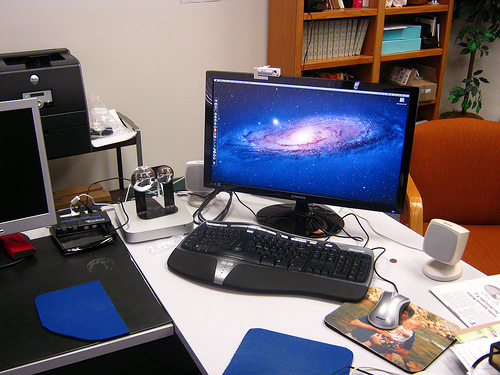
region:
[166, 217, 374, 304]
a black computer keyboard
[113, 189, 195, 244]
an Apple Mac Mini computer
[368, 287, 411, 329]
a silver corded computer mouse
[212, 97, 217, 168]
Apple Mac OS X dock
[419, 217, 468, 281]
a small computer speaker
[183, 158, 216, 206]
a small computer speaker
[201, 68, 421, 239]
a black computer monitor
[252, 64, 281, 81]
a clip on web cam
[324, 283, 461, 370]
a computer mouse pad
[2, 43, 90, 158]
a black laser printer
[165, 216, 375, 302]
Black keyboard for computer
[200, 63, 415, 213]
Black framed computer monitor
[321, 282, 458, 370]
Mouse pad with family photo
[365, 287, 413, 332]
Silver computer mouse on pad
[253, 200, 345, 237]
Black base of computer monitor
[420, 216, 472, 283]
Small white, exterior computer speaker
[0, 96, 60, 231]
Part of silver framed computer monitor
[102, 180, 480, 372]
White tabletop under computer equipment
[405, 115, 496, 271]
Rust colored chair near computer table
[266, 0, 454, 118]
Brown wooden bookcase near computer area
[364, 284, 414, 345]
A silver computer mouse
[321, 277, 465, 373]
A mouse pad with a picture on it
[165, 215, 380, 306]
A black computer keyboard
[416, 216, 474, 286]
A single computer speaker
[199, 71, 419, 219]
A computer screen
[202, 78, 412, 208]
A picture of a galaxy on a desktop computer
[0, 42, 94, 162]
A black printer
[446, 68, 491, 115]
Some green leafs on a plant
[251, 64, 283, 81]
A white small webcam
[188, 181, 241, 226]
A couple of computer cables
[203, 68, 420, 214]
Monitor for a computer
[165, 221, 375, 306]
Keyboard for a computer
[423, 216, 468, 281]
Small speaker for a computer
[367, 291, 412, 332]
Mouse of a computer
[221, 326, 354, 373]
Mousepad for a computer mouse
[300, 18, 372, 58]
Books in a bookshelf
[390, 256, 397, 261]
Penny sitting on a desktop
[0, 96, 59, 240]
Portion of a computer monitor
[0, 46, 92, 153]
Printer for a computer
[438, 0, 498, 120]
Houseplant sitting in the corner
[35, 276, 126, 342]
Blue mouse pad on black desk.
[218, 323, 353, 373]
Blue mouse pad on white desk.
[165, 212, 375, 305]
Black keyboard on desk.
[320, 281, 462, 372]
Mouse pad with photo of man and child.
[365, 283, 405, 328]
Sliver colored mouse on desk.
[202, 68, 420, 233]
Black computer monitor on white desk.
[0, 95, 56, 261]
Computer monitor on black desk.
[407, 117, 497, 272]
Orange chair with wooden arm rest.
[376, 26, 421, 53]
Two light boxes in bookcase.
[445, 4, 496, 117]
Green plant in corner.